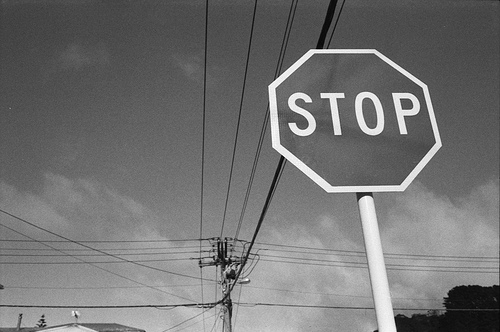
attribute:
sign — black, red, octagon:
[242, 23, 467, 192]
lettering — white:
[294, 85, 417, 146]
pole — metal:
[344, 195, 411, 332]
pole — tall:
[202, 243, 253, 325]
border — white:
[260, 80, 283, 151]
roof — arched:
[81, 314, 140, 331]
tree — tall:
[35, 308, 54, 329]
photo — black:
[2, 5, 489, 322]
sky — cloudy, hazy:
[29, 37, 214, 227]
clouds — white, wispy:
[20, 168, 252, 327]